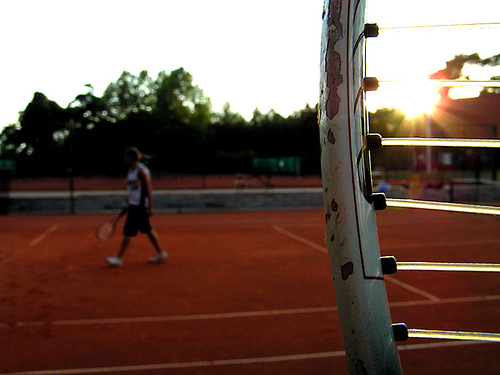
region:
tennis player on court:
[104, 145, 168, 268]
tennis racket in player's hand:
[96, 198, 131, 241]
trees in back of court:
[1, 60, 498, 180]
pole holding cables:
[313, 13, 410, 373]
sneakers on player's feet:
[106, 248, 168, 265]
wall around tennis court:
[2, 186, 499, 213]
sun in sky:
[383, 67, 450, 128]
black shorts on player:
[118, 202, 153, 237]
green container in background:
[248, 154, 301, 179]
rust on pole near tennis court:
[314, 0, 354, 283]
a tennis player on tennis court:
[83, 135, 188, 282]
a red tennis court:
[4, 193, 482, 370]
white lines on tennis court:
[10, 211, 476, 359]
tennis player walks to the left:
[11, 137, 189, 288]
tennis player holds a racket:
[81, 145, 175, 282]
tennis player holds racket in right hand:
[86, 140, 179, 287]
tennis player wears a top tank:
[92, 140, 168, 275]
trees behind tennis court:
[0, 53, 492, 264]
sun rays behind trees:
[360, 38, 497, 175]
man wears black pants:
[100, 137, 175, 277]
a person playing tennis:
[82, 142, 176, 267]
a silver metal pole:
[316, 99, 426, 339]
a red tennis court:
[138, 199, 358, 326]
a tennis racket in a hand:
[96, 196, 144, 242]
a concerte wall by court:
[174, 186, 327, 211]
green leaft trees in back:
[11, 51, 348, 168]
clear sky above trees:
[29, 0, 328, 92]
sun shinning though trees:
[374, 49, 498, 134]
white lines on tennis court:
[105, 276, 326, 337]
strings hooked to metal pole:
[323, 240, 496, 292]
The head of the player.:
[120, 142, 142, 166]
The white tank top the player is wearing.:
[122, 165, 153, 207]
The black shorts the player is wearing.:
[123, 203, 153, 239]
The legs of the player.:
[107, 229, 167, 257]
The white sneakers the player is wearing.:
[110, 248, 176, 267]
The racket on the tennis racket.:
[90, 213, 117, 245]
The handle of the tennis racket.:
[109, 206, 129, 221]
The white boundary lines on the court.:
[15, 209, 419, 372]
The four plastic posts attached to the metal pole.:
[380, 120, 499, 350]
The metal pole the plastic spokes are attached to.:
[314, 4, 400, 374]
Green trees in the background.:
[91, 79, 232, 145]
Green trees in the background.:
[121, 95, 261, 149]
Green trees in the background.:
[81, 105, 234, 137]